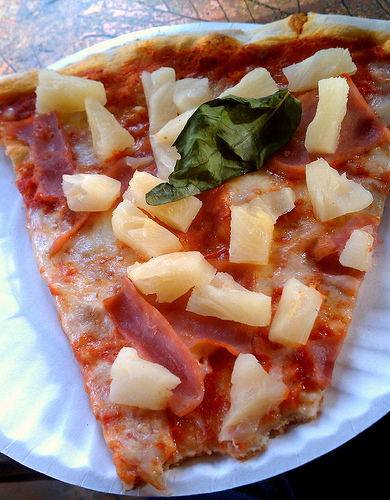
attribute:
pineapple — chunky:
[42, 59, 371, 430]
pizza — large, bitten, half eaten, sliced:
[1, 18, 384, 486]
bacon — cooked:
[26, 105, 352, 423]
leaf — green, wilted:
[146, 78, 290, 195]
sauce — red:
[3, 33, 389, 436]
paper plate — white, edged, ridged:
[2, 146, 388, 499]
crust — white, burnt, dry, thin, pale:
[1, 0, 388, 101]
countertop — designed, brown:
[3, 5, 388, 83]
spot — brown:
[286, 7, 313, 38]